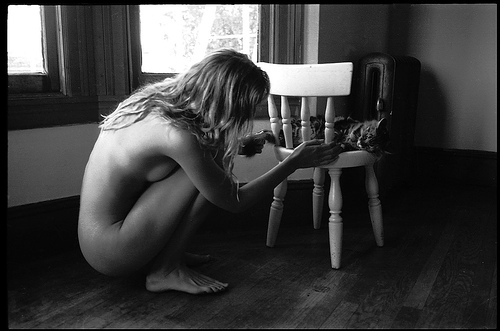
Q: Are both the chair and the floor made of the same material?
A: Yes, both the chair and the floor are made of wood.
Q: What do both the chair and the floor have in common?
A: The material, both the chair and the floor are wooden.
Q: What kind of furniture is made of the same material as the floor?
A: The chair is made of the same material as the floor.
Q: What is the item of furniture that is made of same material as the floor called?
A: The piece of furniture is a chair.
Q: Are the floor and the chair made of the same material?
A: Yes, both the floor and the chair are made of wood.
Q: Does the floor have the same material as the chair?
A: Yes, both the floor and the chair are made of wood.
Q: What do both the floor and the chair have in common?
A: The material, both the floor and the chair are wooden.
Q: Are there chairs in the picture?
A: Yes, there is a chair.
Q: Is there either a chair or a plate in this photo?
A: Yes, there is a chair.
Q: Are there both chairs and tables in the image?
A: No, there is a chair but no tables.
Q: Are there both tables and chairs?
A: No, there is a chair but no tables.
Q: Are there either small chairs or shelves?
A: Yes, there is a small chair.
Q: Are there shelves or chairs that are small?
A: Yes, the chair is small.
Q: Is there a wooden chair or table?
A: Yes, there is a wood chair.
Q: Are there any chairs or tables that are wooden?
A: Yes, the chair is wooden.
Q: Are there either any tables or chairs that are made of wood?
A: Yes, the chair is made of wood.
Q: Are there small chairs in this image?
A: Yes, there is a small chair.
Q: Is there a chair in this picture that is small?
A: Yes, there is a chair that is small.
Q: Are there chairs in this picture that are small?
A: Yes, there is a chair that is small.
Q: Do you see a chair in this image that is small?
A: Yes, there is a chair that is small.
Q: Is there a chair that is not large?
A: Yes, there is a small chair.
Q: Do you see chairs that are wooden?
A: Yes, there is a wood chair.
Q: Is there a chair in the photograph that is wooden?
A: Yes, there is a chair that is wooden.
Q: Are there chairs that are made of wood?
A: Yes, there is a chair that is made of wood.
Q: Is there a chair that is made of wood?
A: Yes, there is a chair that is made of wood.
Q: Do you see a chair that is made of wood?
A: Yes, there is a chair that is made of wood.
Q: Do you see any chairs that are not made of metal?
A: Yes, there is a chair that is made of wood.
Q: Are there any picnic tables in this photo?
A: No, there are no picnic tables.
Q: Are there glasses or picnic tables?
A: No, there are no picnic tables or glasses.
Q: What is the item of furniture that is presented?
A: The piece of furniture is a chair.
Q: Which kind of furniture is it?
A: The piece of furniture is a chair.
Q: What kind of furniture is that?
A: This is a chair.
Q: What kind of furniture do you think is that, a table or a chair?
A: This is a chair.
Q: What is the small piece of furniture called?
A: The piece of furniture is a chair.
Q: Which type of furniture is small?
A: The furniture is a chair.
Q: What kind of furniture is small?
A: The furniture is a chair.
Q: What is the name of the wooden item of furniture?
A: The piece of furniture is a chair.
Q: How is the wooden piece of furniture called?
A: The piece of furniture is a chair.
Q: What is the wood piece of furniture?
A: The piece of furniture is a chair.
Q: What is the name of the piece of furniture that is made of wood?
A: The piece of furniture is a chair.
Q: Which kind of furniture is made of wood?
A: The furniture is a chair.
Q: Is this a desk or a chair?
A: This is a chair.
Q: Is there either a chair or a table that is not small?
A: No, there is a chair but it is small.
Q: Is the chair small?
A: Yes, the chair is small.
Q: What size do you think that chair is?
A: The chair is small.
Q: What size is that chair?
A: The chair is small.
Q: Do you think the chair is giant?
A: No, the chair is small.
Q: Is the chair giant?
A: No, the chair is small.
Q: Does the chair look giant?
A: No, the chair is small.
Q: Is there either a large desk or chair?
A: No, there is a chair but it is small.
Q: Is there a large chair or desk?
A: No, there is a chair but it is small.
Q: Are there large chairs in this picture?
A: No, there is a chair but it is small.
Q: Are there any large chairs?
A: No, there is a chair but it is small.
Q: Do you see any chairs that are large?
A: No, there is a chair but it is small.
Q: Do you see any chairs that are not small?
A: No, there is a chair but it is small.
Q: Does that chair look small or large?
A: The chair is small.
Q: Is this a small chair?
A: Yes, this is a small chair.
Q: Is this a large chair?
A: No, this is a small chair.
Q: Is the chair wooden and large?
A: No, the chair is wooden but small.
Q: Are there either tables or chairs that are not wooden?
A: No, there is a chair but it is wooden.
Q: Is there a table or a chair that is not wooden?
A: No, there is a chair but it is wooden.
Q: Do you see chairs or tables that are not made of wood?
A: No, there is a chair but it is made of wood.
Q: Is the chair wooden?
A: Yes, the chair is wooden.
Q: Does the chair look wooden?
A: Yes, the chair is wooden.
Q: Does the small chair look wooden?
A: Yes, the chair is wooden.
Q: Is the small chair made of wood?
A: Yes, the chair is made of wood.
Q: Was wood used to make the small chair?
A: Yes, the chair is made of wood.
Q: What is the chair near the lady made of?
A: The chair is made of wood.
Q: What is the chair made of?
A: The chair is made of wood.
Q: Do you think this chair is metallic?
A: No, the chair is wooden.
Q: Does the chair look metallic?
A: No, the chair is wooden.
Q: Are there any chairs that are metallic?
A: No, there is a chair but it is wooden.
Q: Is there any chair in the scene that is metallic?
A: No, there is a chair but it is wooden.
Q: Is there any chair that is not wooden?
A: No, there is a chair but it is wooden.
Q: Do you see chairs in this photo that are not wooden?
A: No, there is a chair but it is wooden.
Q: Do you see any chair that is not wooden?
A: No, there is a chair but it is wooden.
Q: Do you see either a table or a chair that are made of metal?
A: No, there is a chair but it is made of wood.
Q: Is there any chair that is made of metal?
A: No, there is a chair but it is made of wood.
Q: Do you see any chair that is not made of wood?
A: No, there is a chair but it is made of wood.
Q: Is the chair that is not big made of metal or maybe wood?
A: The chair is made of wood.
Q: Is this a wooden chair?
A: Yes, this is a wooden chair.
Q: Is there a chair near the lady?
A: Yes, there is a chair near the lady.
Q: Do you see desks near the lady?
A: No, there is a chair near the lady.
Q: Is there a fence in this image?
A: No, there are no fences.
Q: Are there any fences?
A: No, there are no fences.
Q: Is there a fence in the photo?
A: No, there are no fences.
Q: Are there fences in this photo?
A: No, there are no fences.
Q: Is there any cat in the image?
A: Yes, there is a cat.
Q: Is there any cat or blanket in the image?
A: Yes, there is a cat.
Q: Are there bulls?
A: No, there are no bulls.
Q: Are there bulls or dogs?
A: No, there are no bulls or dogs.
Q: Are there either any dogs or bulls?
A: No, there are no bulls or dogs.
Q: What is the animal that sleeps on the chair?
A: The animal is a cat.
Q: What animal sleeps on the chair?
A: The animal is a cat.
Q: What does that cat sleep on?
A: The cat sleeps on the chair.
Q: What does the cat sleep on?
A: The cat sleeps on the chair.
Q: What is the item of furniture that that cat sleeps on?
A: The piece of furniture is a chair.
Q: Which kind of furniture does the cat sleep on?
A: The cat sleeps on the chair.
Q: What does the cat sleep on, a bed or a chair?
A: The cat sleeps on a chair.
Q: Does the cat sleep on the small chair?
A: Yes, the cat sleeps on the chair.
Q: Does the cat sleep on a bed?
A: No, the cat sleeps on the chair.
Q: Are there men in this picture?
A: No, there are no men.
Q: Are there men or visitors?
A: No, there are no men or visitors.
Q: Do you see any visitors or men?
A: No, there are no men or visitors.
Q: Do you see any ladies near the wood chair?
A: Yes, there is a lady near the chair.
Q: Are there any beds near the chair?
A: No, there is a lady near the chair.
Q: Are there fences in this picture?
A: No, there are no fences.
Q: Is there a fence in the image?
A: No, there are no fences.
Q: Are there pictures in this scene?
A: No, there are no pictures.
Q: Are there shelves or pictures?
A: No, there are no pictures or shelves.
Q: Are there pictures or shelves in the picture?
A: No, there are no pictures or shelves.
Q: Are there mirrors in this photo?
A: No, there are no mirrors.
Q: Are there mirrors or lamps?
A: No, there are no mirrors or lamps.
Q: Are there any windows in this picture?
A: Yes, there is a window.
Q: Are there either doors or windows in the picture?
A: Yes, there is a window.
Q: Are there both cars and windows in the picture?
A: No, there is a window but no cars.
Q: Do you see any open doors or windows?
A: Yes, there is an open window.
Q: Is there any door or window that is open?
A: Yes, the window is open.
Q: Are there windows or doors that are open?
A: Yes, the window is open.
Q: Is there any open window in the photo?
A: Yes, there is an open window.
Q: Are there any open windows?
A: Yes, there is an open window.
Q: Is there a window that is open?
A: Yes, there is a window that is open.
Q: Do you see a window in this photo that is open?
A: Yes, there is a window that is open.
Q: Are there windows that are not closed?
A: Yes, there is a open window.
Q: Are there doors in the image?
A: No, there are no doors.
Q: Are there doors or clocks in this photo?
A: No, there are no doors or clocks.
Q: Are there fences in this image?
A: No, there are no fences.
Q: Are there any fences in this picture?
A: No, there are no fences.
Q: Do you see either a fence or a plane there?
A: No, there are no fences or airplanes.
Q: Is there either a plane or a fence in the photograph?
A: No, there are no fences or airplanes.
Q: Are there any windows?
A: Yes, there is a window.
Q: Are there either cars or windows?
A: Yes, there is a window.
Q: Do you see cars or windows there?
A: Yes, there is a window.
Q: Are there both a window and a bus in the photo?
A: No, there is a window but no buses.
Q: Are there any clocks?
A: No, there are no clocks.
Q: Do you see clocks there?
A: No, there are no clocks.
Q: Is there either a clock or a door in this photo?
A: No, there are no clocks or doors.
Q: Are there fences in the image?
A: No, there are no fences.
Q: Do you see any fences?
A: No, there are no fences.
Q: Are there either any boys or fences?
A: No, there are no fences or boys.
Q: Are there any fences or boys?
A: No, there are no fences or boys.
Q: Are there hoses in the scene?
A: No, there are no hoses.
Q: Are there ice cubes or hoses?
A: No, there are no hoses or ice cubes.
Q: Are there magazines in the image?
A: No, there are no magazines.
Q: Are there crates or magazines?
A: No, there are no magazines or crates.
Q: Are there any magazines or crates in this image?
A: No, there are no magazines or crates.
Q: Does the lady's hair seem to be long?
A: Yes, the hair is long.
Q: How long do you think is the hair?
A: The hair is long.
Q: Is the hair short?
A: No, the hair is long.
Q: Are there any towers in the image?
A: No, there are no towers.